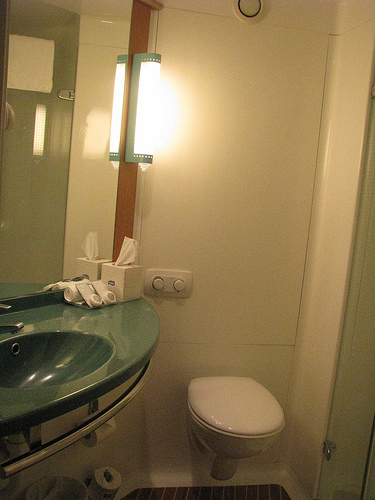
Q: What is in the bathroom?
A: A green sink.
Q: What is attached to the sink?
A: A shiny chrome bar.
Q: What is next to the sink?
A: A white toilet.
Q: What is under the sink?
A: A rail.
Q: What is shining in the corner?
A: A light.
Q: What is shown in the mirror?
A: Reflection of door.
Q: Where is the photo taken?
A: A bathroom.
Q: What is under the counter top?
A: A metal rail.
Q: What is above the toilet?
A: Flusher buttons.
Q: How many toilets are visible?
A: One.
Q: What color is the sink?
A: Green.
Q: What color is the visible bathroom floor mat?
A: Brown.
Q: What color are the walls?
A: White.